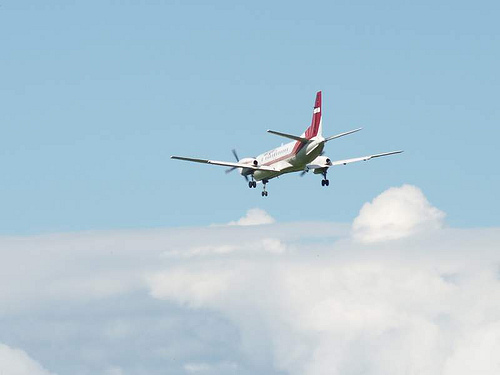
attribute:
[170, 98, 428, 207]
plane — flying, white, landing, high, red, large, black, single engine, winged, small, two engine, windowed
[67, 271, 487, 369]
clouds — white, fluffy, gray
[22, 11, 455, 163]
sky — blue, cloudy, daytime, sunny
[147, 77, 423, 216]
airplane — white, cruising, landing, flying, red, winged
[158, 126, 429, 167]
wing — red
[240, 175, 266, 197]
wheel — black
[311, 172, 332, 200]
wheel — black